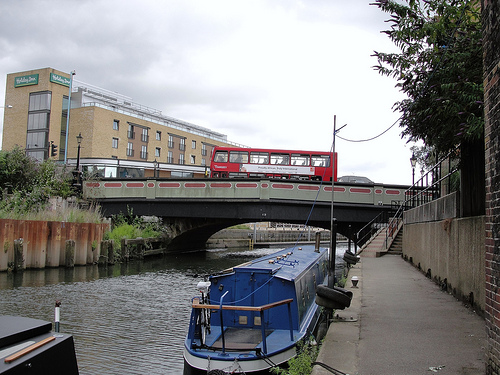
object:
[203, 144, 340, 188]
bus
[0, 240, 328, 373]
river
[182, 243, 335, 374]
boat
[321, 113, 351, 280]
light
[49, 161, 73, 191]
bush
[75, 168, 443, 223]
bridge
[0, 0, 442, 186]
sky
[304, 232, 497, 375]
street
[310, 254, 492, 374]
sidewalk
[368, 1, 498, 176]
tree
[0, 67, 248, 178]
building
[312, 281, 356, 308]
tires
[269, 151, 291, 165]
window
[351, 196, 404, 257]
stair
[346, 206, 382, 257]
railing